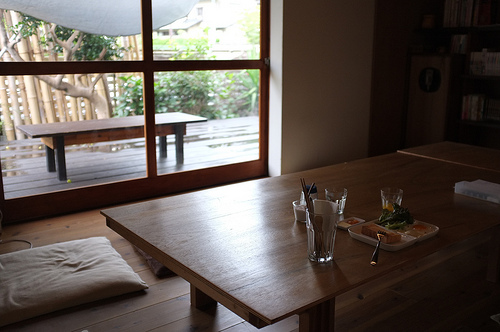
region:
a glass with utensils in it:
[304, 191, 334, 264]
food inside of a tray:
[347, 204, 437, 249]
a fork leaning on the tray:
[362, 223, 391, 273]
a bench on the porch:
[22, 99, 217, 161]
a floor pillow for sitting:
[2, 235, 120, 302]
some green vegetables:
[377, 205, 408, 223]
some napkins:
[450, 172, 490, 199]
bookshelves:
[422, 19, 481, 121]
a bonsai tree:
[0, 15, 111, 105]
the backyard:
[152, 5, 243, 102]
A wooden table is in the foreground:
[75, 125, 495, 327]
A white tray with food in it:
[345, 195, 445, 270]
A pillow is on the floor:
[0, 225, 155, 330]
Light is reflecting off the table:
[198, 172, 279, 284]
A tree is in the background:
[0, 15, 125, 116]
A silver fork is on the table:
[365, 221, 395, 268]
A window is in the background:
[0, 0, 265, 170]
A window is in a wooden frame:
[0, 0, 265, 180]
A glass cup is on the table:
[300, 196, 340, 268]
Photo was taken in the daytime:
[5, 2, 267, 188]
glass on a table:
[300, 195, 348, 270]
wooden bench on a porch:
[10, 91, 211, 193]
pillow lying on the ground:
[0, 224, 147, 319]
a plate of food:
[345, 189, 452, 273]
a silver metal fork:
[360, 226, 397, 268]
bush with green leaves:
[112, 39, 247, 121]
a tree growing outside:
[0, 3, 134, 127]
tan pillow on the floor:
[0, 213, 162, 314]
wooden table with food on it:
[95, 130, 497, 330]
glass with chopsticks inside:
[297, 172, 352, 274]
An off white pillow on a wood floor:
[0, 228, 147, 324]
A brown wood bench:
[10, 105, 210, 180]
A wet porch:
[1, 116, 271, 196]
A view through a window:
[0, 1, 260, 191]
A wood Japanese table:
[96, 135, 497, 327]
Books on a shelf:
[449, 87, 499, 139]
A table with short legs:
[94, 136, 499, 327]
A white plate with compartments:
[346, 202, 443, 253]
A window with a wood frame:
[3, 1, 267, 221]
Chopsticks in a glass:
[281, 172, 371, 262]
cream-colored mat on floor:
[3, 234, 145, 319]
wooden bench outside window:
[18, 106, 208, 183]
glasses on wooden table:
[286, 181, 406, 274]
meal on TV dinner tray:
[338, 210, 438, 250]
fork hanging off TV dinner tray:
[371, 227, 388, 267]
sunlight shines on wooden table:
[188, 164, 294, 324]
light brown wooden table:
[97, 137, 497, 324]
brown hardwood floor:
[4, 189, 498, 329]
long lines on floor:
[0, 208, 497, 328]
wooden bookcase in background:
[412, 3, 497, 144]